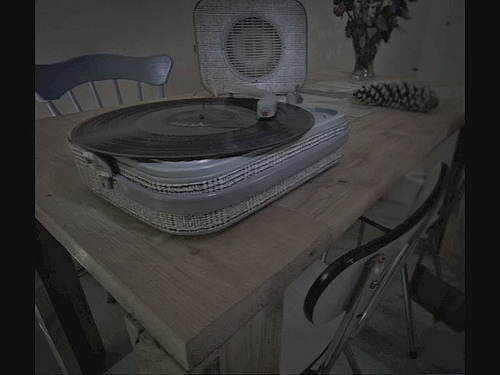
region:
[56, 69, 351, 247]
This is a record player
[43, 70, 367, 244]
The record player shows signs of old age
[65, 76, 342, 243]
There is dust on the player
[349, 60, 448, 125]
A cone on the table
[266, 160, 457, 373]
There are chairs underneath the table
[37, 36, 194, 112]
This chair is wooden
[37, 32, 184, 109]
White is the color of the chair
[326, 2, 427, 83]
Plants in a vase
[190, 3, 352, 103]
The fan is old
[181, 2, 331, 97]
There are signs of wear and tear on the fan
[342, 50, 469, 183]
pine cone lying on a table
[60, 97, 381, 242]
old record playing sitting on table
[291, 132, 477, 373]
black and white chair at a table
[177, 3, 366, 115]
fan sitting on a table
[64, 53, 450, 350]
wooden table with many items on the table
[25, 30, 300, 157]
white wooden chair sitting at a table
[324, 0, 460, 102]
vase of flowers sitting at a table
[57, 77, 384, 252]
old record player with record playing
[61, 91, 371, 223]
78 size record on old record player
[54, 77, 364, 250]
a record player set up to play old 78 rpm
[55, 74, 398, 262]
record player is white and black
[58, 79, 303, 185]
the record is dusty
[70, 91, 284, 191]
the record is black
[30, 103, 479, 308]
table is made of wood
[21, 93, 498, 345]
the table is brown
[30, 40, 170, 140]
the chair is white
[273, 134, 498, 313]
the chair is black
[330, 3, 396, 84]
plant is on counter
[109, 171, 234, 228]
gray lining around record player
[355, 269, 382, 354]
metal pieces in back of chair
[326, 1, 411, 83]
A vase with flowers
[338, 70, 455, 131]
A pine cone sitting on a table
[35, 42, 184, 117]
A wooden chair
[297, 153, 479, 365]
A metal chair at the table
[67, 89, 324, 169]
A 33 rpm record playing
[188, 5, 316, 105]
A speaker for listening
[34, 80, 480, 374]
A wooden table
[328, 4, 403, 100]
A flower vase sitting on a tablew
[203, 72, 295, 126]
The arm of a record player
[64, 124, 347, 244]
A record player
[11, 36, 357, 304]
very old record player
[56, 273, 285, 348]
wooden table beneath player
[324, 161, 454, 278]
black trim to chair backing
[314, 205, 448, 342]
metal part of chair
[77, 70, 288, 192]
black record on top of player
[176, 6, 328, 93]
small speaker in background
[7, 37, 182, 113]
front end of a chair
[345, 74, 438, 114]
large pine cone on top of table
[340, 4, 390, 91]
vase in corner of table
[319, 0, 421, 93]
vase with plants in it